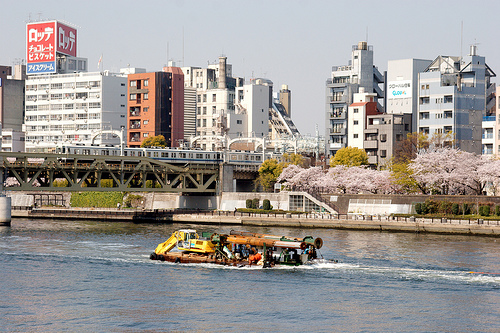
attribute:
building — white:
[322, 34, 387, 172]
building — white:
[414, 51, 486, 162]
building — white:
[24, 70, 126, 162]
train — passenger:
[52, 143, 274, 171]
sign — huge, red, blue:
[26, 20, 78, 72]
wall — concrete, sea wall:
[6, 190, 499, 236]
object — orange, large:
[247, 252, 262, 263]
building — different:
[124, 64, 185, 144]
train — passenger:
[59, 143, 276, 161]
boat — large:
[148, 228, 335, 273]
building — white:
[20, 74, 125, 149]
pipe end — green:
[300, 236, 327, 249]